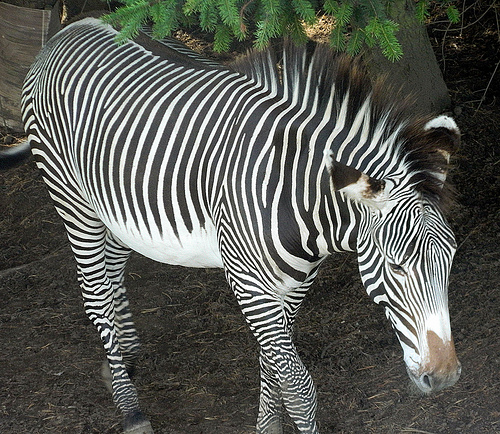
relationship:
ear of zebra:
[322, 152, 392, 212] [21, 15, 461, 430]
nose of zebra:
[421, 365, 462, 388] [21, 15, 461, 430]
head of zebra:
[321, 117, 467, 393] [21, 15, 461, 430]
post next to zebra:
[0, 8, 63, 152] [21, 15, 461, 430]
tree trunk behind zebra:
[348, 2, 444, 116] [21, 15, 461, 430]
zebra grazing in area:
[21, 15, 461, 430] [0, 49, 490, 429]